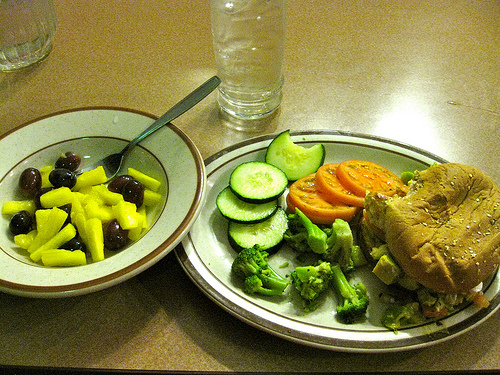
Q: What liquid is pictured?
A: Water.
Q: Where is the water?
A: On table.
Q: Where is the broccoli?
A: On plate.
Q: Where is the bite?
A: Hamburger.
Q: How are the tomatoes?
A: Stacked.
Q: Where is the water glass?
A: On the table.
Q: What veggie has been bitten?
A: Cucumbers.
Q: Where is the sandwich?
A: On the plate.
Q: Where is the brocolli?
A: On the plate.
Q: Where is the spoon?
A: In the bowl.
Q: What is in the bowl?
A: Fruit.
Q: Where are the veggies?
A: In the plate.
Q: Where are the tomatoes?
A: On the plate.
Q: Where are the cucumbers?
A: On the plate.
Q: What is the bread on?
A: The sandwich.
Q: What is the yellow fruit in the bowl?
A: Pineapple.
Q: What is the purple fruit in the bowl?
A: Grapes.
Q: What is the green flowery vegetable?
A: Broccoli.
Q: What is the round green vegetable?
A: Cucumber.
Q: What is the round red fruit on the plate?
A: Tomato.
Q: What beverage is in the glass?
A: Water.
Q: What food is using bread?
A: Sandwich.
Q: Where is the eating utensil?
A: In the bowl.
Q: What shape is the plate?
A: Circle.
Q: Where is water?
A: In a glass.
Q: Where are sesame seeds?
A: On hamburger bun.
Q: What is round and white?
A: Plates.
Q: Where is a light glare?
A: On table.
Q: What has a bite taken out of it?
A: Cucumber slice.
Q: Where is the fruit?
A: On left plate.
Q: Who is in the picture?
A: No one.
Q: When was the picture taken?
A: Mealtime.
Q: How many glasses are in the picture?
A: Two.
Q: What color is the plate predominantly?
A: White.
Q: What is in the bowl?
A: Fruit.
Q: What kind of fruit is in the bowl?
A: Pineapple and grapes.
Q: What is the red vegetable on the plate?
A: Tomatoes.